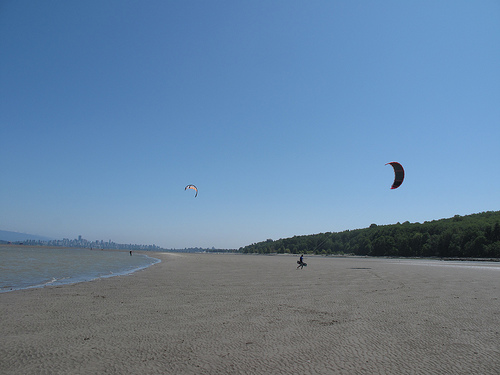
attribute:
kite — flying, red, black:
[383, 151, 415, 198]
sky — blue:
[243, 62, 298, 113]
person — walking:
[293, 249, 323, 276]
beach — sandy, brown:
[164, 273, 248, 347]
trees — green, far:
[377, 218, 459, 247]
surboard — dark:
[300, 262, 307, 269]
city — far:
[62, 224, 97, 247]